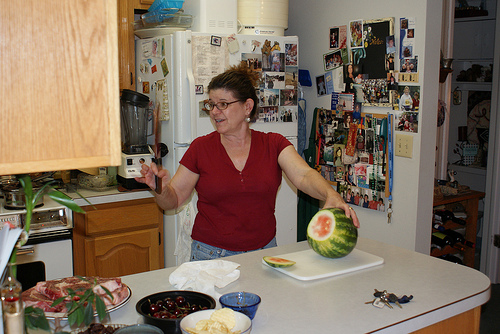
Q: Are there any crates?
A: No, there are no crates.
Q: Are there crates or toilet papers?
A: No, there are no crates or toilet papers.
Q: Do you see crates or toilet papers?
A: No, there are no crates or toilet papers.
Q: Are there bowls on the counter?
A: Yes, there is a bowl on the counter.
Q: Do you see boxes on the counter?
A: No, there is a bowl on the counter.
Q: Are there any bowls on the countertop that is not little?
A: Yes, there is a bowl on the countertop.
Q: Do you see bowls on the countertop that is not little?
A: Yes, there is a bowl on the countertop.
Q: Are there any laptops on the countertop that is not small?
A: No, there is a bowl on the countertop.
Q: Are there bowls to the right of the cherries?
A: Yes, there is a bowl to the right of the cherries.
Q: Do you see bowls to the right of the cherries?
A: Yes, there is a bowl to the right of the cherries.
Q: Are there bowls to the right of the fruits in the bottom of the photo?
A: Yes, there is a bowl to the right of the cherries.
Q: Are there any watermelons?
A: Yes, there is a watermelon.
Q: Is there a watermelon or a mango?
A: Yes, there is a watermelon.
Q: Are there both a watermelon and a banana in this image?
A: No, there is a watermelon but no bananas.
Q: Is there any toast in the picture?
A: No, there are no toasts.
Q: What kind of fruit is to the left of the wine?
A: The fruit is a watermelon.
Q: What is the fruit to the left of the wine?
A: The fruit is a watermelon.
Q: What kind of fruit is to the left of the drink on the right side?
A: The fruit is a watermelon.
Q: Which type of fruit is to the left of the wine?
A: The fruit is a watermelon.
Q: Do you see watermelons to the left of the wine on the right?
A: Yes, there is a watermelon to the left of the wine.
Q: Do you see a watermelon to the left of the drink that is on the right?
A: Yes, there is a watermelon to the left of the wine.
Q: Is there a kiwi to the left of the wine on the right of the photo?
A: No, there is a watermelon to the left of the wine.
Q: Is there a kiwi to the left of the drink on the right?
A: No, there is a watermelon to the left of the wine.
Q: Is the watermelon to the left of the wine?
A: Yes, the watermelon is to the left of the wine.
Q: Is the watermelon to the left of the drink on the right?
A: Yes, the watermelon is to the left of the wine.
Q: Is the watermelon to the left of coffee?
A: No, the watermelon is to the left of the wine.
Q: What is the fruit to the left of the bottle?
A: The fruit is a watermelon.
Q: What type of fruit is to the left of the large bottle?
A: The fruit is a watermelon.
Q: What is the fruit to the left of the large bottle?
A: The fruit is a watermelon.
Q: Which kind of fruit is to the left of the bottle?
A: The fruit is a watermelon.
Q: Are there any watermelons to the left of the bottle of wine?
A: Yes, there is a watermelon to the left of the bottle.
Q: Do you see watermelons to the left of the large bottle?
A: Yes, there is a watermelon to the left of the bottle.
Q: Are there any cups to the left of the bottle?
A: No, there is a watermelon to the left of the bottle.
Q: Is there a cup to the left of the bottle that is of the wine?
A: No, there is a watermelon to the left of the bottle.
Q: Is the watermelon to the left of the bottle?
A: Yes, the watermelon is to the left of the bottle.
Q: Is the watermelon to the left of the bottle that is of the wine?
A: Yes, the watermelon is to the left of the bottle.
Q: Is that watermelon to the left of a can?
A: No, the watermelon is to the left of the bottle.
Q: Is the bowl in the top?
A: No, the bowl is in the bottom of the image.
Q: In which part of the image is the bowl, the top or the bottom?
A: The bowl is in the bottom of the image.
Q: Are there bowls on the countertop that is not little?
A: Yes, there is a bowl on the countertop.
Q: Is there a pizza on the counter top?
A: No, there is a bowl on the counter top.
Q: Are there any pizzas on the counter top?
A: No, there is a bowl on the counter top.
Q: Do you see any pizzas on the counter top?
A: No, there is a bowl on the counter top.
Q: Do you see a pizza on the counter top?
A: No, there is a bowl on the counter top.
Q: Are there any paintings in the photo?
A: No, there are no paintings.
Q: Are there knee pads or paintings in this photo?
A: No, there are no paintings or knee pads.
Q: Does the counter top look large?
A: Yes, the counter top is large.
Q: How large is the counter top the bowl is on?
A: The counter top is large.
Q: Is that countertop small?
A: No, the countertop is large.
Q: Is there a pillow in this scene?
A: No, there are no pillows.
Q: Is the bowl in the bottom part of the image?
A: Yes, the bowl is in the bottom of the image.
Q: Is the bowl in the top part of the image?
A: No, the bowl is in the bottom of the image.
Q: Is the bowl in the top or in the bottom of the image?
A: The bowl is in the bottom of the image.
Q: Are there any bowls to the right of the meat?
A: Yes, there is a bowl to the right of the meat.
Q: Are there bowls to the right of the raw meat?
A: Yes, there is a bowl to the right of the meat.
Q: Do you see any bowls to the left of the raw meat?
A: No, the bowl is to the right of the meat.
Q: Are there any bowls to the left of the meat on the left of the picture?
A: No, the bowl is to the right of the meat.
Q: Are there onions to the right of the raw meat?
A: No, there is a bowl to the right of the meat.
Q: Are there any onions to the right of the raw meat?
A: No, there is a bowl to the right of the meat.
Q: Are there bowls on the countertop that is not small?
A: Yes, there is a bowl on the counter top.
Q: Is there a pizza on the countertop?
A: No, there is a bowl on the countertop.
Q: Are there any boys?
A: No, there are no boys.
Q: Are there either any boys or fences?
A: No, there are no boys or fences.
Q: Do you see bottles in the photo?
A: Yes, there is a bottle.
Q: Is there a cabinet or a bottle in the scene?
A: Yes, there is a bottle.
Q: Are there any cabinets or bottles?
A: Yes, there is a bottle.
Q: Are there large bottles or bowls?
A: Yes, there is a large bottle.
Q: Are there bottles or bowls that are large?
A: Yes, the bottle is large.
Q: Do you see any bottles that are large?
A: Yes, there is a large bottle.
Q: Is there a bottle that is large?
A: Yes, there is a bottle that is large.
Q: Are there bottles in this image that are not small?
A: Yes, there is a large bottle.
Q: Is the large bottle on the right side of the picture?
A: Yes, the bottle is on the right of the image.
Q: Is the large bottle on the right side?
A: Yes, the bottle is on the right of the image.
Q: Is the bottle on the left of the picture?
A: No, the bottle is on the right of the image.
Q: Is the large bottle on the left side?
A: No, the bottle is on the right of the image.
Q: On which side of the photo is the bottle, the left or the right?
A: The bottle is on the right of the image.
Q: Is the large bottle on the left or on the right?
A: The bottle is on the right of the image.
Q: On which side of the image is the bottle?
A: The bottle is on the right of the image.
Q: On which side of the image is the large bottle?
A: The bottle is on the right of the image.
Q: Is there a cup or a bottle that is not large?
A: No, there is a bottle but it is large.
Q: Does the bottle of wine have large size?
A: Yes, the bottle is large.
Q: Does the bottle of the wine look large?
A: Yes, the bottle is large.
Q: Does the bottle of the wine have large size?
A: Yes, the bottle is large.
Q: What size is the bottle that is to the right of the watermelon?
A: The bottle is large.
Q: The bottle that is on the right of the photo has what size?
A: The bottle is large.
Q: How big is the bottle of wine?
A: The bottle is large.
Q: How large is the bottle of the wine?
A: The bottle is large.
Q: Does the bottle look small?
A: No, the bottle is large.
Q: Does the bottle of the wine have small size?
A: No, the bottle is large.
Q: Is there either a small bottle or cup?
A: No, there is a bottle but it is large.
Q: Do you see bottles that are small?
A: No, there is a bottle but it is large.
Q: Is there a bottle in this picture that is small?
A: No, there is a bottle but it is large.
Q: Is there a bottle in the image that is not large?
A: No, there is a bottle but it is large.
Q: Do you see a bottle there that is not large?
A: No, there is a bottle but it is large.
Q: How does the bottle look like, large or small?
A: The bottle is large.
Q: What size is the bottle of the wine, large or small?
A: The bottle is large.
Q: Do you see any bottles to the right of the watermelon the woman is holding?
A: Yes, there is a bottle to the right of the watermelon.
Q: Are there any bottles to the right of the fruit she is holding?
A: Yes, there is a bottle to the right of the watermelon.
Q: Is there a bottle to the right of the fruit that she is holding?
A: Yes, there is a bottle to the right of the watermelon.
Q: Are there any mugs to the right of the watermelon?
A: No, there is a bottle to the right of the watermelon.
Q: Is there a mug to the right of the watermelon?
A: No, there is a bottle to the right of the watermelon.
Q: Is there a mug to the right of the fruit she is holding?
A: No, there is a bottle to the right of the watermelon.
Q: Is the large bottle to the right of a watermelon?
A: Yes, the bottle is to the right of a watermelon.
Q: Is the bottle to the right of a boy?
A: No, the bottle is to the right of a watermelon.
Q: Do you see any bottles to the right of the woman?
A: Yes, there is a bottle to the right of the woman.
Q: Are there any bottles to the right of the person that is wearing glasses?
A: Yes, there is a bottle to the right of the woman.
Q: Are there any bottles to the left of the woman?
A: No, the bottle is to the right of the woman.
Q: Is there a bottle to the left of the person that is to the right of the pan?
A: No, the bottle is to the right of the woman.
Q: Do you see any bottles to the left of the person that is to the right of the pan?
A: No, the bottle is to the right of the woman.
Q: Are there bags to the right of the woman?
A: No, there is a bottle to the right of the woman.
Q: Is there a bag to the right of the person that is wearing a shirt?
A: No, there is a bottle to the right of the woman.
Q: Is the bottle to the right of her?
A: Yes, the bottle is to the right of a woman.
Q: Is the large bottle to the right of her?
A: Yes, the bottle is to the right of a woman.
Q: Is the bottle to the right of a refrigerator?
A: No, the bottle is to the right of a woman.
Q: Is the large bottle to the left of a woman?
A: No, the bottle is to the right of a woman.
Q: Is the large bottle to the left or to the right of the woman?
A: The bottle is to the right of the woman.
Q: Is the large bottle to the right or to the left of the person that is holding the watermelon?
A: The bottle is to the right of the woman.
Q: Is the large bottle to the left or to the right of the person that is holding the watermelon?
A: The bottle is to the right of the woman.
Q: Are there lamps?
A: No, there are no lamps.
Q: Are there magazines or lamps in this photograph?
A: No, there are no lamps or magazines.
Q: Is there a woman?
A: Yes, there is a woman.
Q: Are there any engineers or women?
A: Yes, there is a woman.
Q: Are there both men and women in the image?
A: No, there is a woman but no men.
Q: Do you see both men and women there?
A: No, there is a woman but no men.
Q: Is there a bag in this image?
A: No, there are no bags.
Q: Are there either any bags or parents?
A: No, there are no bags or parents.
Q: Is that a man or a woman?
A: That is a woman.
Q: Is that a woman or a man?
A: That is a woman.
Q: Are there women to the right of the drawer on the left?
A: Yes, there is a woman to the right of the drawer.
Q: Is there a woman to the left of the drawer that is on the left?
A: No, the woman is to the right of the drawer.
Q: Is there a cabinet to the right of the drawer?
A: No, there is a woman to the right of the drawer.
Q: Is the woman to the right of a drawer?
A: Yes, the woman is to the right of a drawer.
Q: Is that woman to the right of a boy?
A: No, the woman is to the right of a drawer.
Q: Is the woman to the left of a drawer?
A: No, the woman is to the right of a drawer.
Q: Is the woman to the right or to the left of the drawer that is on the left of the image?
A: The woman is to the right of the drawer.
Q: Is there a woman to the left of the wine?
A: Yes, there is a woman to the left of the wine.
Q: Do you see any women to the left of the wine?
A: Yes, there is a woman to the left of the wine.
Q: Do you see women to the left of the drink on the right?
A: Yes, there is a woman to the left of the wine.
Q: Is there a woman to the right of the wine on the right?
A: No, the woman is to the left of the wine.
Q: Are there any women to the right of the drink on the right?
A: No, the woman is to the left of the wine.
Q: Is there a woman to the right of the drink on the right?
A: No, the woman is to the left of the wine.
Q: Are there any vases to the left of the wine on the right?
A: No, there is a woman to the left of the wine.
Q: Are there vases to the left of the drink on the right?
A: No, there is a woman to the left of the wine.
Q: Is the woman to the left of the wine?
A: Yes, the woman is to the left of the wine.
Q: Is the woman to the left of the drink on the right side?
A: Yes, the woman is to the left of the wine.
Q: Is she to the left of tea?
A: No, the woman is to the left of the wine.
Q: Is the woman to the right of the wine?
A: No, the woman is to the left of the wine.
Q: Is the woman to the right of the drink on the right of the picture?
A: No, the woman is to the left of the wine.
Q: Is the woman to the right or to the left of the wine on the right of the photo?
A: The woman is to the left of the wine.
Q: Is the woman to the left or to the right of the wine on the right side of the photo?
A: The woman is to the left of the wine.